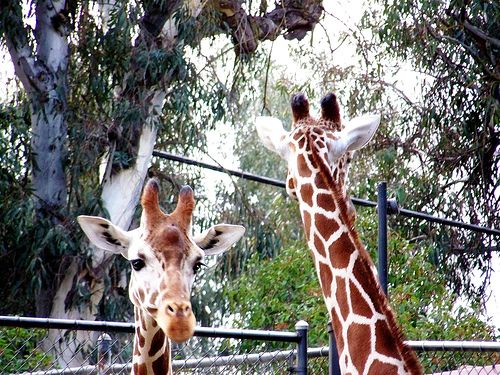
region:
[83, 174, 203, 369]
head of the giraffe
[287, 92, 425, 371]
neck and head of the giraffe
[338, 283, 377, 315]
spot on the giraffe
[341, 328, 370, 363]
spot on the giraffe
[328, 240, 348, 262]
spot on the giraffe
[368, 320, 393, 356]
spot on the giraffe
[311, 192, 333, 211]
spot on the giraffe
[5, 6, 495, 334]
bright sky through trees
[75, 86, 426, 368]
giraffes standing near each other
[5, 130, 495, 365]
railings over metal fencing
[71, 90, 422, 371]
giraffes looking in different directions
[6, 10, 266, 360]
trees with thin drooping leaves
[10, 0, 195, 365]
white trunk curved in front of gray trunk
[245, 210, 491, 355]
green bush behind giraffe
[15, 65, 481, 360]
busy background of trunks, leaves and light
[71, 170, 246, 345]
calm and peaceful face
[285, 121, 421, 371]
long, smooth and soft neck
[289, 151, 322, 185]
Brown spot on an animal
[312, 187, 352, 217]
Brown spot on an animal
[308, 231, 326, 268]
Brown spot on an animal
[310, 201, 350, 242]
Brown spot on an animal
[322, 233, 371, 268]
Brown spot on an animal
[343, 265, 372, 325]
Brown spot on an animal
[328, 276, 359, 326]
Brown spot on an animal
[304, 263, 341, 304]
Brown spot on an animal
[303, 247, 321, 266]
Brown spot on an animal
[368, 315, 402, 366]
Brown spot on an animal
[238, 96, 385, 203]
head of a giraffe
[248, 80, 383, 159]
head of a giraffe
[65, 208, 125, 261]
ear of a giraffe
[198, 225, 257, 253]
ear of a giraffe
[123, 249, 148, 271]
eye of a giraffe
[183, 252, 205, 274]
eye of a giraffe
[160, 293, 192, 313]
nose of a giraffe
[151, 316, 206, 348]
mouth of a giraffe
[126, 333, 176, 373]
neck of a giraffe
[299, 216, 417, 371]
neck of a giraffe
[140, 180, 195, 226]
horns on giraffes head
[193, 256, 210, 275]
giraffe with long eyelashes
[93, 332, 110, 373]
rusty metal fence pole by giraffe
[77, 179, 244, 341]
giraffe by fence facing the camera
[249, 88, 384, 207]
taller giraffe turned away from the camera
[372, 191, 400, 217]
speaker on metal pole by giraffe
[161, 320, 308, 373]
metal chain link fence by giraffe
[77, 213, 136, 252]
giraffe with big white an black ears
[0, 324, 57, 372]
green shrubs behind chain link fence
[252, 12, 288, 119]
green vines growing from large tree